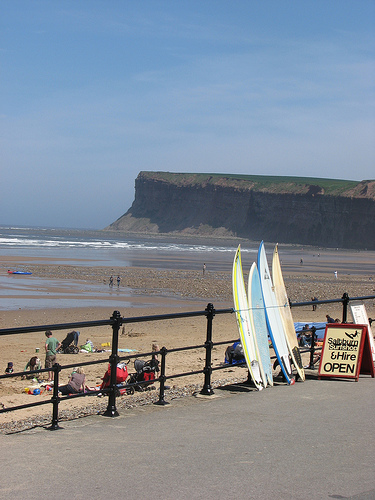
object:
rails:
[0, 292, 374, 429]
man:
[43, 328, 61, 381]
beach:
[0, 241, 373, 419]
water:
[3, 233, 89, 250]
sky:
[1, 3, 374, 176]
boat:
[6, 262, 33, 278]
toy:
[21, 386, 42, 397]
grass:
[246, 176, 290, 192]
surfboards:
[230, 235, 307, 395]